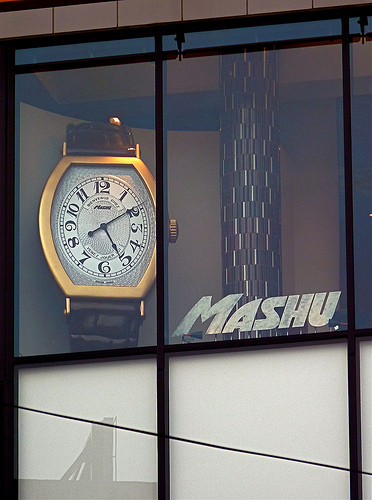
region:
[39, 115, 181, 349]
a large watch in an advertisement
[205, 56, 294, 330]
a pole inside the room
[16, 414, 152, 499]
a reflection of a building in the window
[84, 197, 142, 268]
the hands of the watch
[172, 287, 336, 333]
a name of a business in he window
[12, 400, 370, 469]
a wire in front of the building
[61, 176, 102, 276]
some numbers on the watch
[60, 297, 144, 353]
part of the strap of the watch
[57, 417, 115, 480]
a billboard in the reflection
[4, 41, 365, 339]
a business in one of the rooms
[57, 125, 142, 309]
large photo of watch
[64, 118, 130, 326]
watch is gold and brown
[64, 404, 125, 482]
reflection in lower window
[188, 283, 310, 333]
words mashu on window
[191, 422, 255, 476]
dark line through window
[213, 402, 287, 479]
window is white and shiny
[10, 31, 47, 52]
black frame around window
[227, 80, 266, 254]
black and gray cylinder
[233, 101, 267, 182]
tall black and gray column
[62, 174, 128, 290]
watch has black and white face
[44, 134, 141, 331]
this is a watch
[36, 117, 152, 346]
the watch is big in size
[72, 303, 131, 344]
this is the hand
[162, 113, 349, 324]
this is a window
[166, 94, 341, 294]
the glass is clear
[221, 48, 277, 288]
this is a pillar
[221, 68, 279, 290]
the pillar is wide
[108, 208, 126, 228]
this is the minute hand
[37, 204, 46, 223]
the frame is metallic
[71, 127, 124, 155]
the hand is brown in color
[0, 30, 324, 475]
a clock behind a window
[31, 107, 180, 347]
clock of wrist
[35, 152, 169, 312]
frame of clock is color gold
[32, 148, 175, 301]
clock has cardinal numbers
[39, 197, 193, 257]
knob clock on right side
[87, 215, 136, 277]
hour hand of clock is in 5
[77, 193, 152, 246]
minute hand of clock is in 2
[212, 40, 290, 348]
a pole behind a window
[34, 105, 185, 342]
strap of clock is leather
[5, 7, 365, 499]
a window with black frame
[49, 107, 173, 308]
this is a wrist watch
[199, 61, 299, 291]
this is a pillar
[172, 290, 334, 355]
this is a writing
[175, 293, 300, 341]
the writing is in white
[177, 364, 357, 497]
this is a glass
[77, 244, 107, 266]
this is the writing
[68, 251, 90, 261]
the writing is in black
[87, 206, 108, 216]
the watch is white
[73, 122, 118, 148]
this is a the leather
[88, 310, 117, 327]
the leather is brown in color